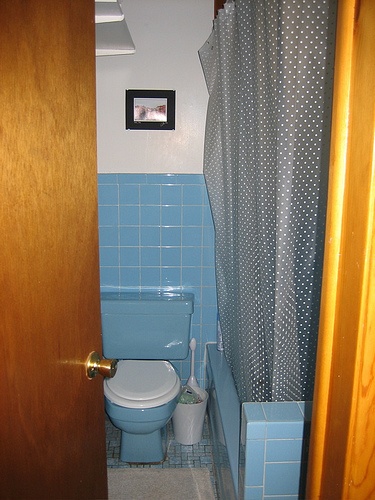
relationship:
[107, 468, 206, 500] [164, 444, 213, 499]
mat on floor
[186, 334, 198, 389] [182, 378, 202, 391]
handle in container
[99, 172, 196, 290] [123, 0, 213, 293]
tile on wall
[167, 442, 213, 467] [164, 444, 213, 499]
tile on floor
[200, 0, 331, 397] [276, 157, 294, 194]
curtain with polka dots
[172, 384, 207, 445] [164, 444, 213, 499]
trash can on floor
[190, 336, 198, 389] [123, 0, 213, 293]
brush on wall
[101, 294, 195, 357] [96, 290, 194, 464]
tank for toilet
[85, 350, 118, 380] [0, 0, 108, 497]
knob for door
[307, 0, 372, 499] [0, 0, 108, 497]
frame for door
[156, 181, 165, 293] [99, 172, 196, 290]
grout on tile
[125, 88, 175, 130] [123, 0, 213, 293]
picture on wall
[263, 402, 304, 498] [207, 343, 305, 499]
tiles on tub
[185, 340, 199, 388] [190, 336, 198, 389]
handle of brush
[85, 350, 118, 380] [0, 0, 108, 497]
knob on door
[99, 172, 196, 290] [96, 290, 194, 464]
tile behind toilet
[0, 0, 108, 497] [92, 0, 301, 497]
door for bathroom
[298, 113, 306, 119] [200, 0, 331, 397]
polka dot on curtain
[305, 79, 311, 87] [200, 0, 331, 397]
polka dot on curtain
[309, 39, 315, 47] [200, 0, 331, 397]
polka dot on curtain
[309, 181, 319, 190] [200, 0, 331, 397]
polka dot on curtain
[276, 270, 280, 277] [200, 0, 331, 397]
polka dot on curtain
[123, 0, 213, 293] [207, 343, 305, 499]
wall by tub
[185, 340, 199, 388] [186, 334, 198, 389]
handle of handle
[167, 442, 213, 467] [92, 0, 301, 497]
tile in bathroom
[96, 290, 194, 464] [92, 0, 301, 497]
toilet in bathroom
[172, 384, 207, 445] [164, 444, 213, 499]
trash can on ground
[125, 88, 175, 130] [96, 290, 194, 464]
picture above toilet